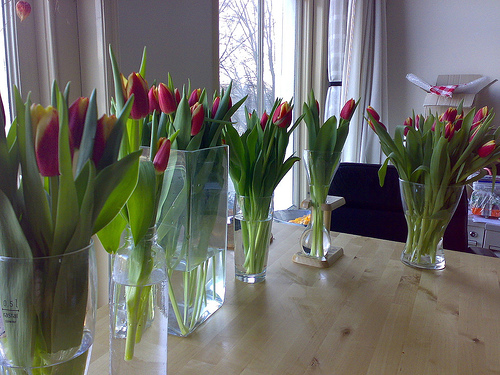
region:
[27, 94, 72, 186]
violet flower in glass vase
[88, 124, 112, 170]
violet flower in glass vase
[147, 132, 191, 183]
violet flower in glass vase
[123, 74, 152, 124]
violet flower in glass vase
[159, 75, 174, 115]
violet flower in glass vase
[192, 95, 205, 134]
violet flower in glass vase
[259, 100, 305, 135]
violet flower in glass vase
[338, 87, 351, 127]
violet flower in glass vase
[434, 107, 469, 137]
violet flower in glass vase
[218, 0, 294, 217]
daylight through window glass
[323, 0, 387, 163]
curtain pulled back from window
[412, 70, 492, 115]
open flaps of cardboard box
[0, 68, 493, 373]
flowers in glass containers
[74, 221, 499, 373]
surface of wood table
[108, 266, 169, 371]
water in glass container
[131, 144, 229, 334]
square glass vase with water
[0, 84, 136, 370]
tulips and leaves in vase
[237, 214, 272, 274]
flower stems in water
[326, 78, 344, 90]
tie back on curtain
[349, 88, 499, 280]
Red tulips in a clear glass vase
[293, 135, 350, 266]
Red tulips in a clear glass vase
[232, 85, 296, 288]
Red tulips in a clear glass vase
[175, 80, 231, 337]
Red tulips in a clear glass vase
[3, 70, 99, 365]
Red tulips in a clear glass vase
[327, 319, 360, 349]
dark knot on light wood table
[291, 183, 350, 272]
wood stand holding glass vase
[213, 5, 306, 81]
Window behind table holding vases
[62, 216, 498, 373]
natural wood table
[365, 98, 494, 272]
vase with pink tulips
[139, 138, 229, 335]
clear square glass vase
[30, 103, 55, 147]
yellow center on pink tulip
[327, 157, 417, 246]
blue chair next to table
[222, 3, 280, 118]
tree with no leaves visible through window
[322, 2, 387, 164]
plaid drape tied open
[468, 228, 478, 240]
silver cabinet lock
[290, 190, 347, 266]
vase on wooden pedestal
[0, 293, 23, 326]
measuring marker on vase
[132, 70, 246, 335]
Flowers in a vase on a table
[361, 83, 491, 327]
Flowers in a vase on a table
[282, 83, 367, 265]
Flowers in a vase on a table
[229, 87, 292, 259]
Flowers in a vase on a table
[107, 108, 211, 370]
Flowers in a vase on a table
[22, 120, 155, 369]
Flowers in a vase on a table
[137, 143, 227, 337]
cube shaped glass vase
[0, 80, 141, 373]
a vase of yellow tipped pink tulips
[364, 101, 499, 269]
Vase of pink flowers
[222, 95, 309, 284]
Vase of pink flowers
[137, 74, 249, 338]
Vase of pink flowers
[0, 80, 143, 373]
Vase of pink flowers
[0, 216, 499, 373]
Light wooden table with flower vases on it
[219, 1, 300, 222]
Large glass window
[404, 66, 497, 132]
Open cardboard box on table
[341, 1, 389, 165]
Cream colored curtain on window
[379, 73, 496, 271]
bouquet of flowers in the vase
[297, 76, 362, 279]
bouquet of flowers in the vase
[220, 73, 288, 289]
bouquet of flowers in the vase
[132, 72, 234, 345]
bouquet of flowers in the vase